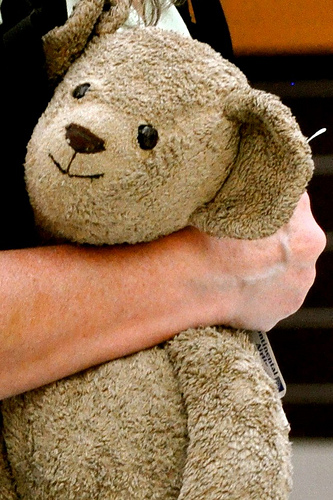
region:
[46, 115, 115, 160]
a large brown nose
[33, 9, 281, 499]
a tan teddy bear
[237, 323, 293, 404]
a white card with black letters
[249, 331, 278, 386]
black letters on white surface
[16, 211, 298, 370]
an arm around the neck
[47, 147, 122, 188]
small mouth of bear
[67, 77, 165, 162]
two black eyes on bear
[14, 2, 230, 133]
a white and black shirt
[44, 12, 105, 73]
a folded ear on bear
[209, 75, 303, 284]
a round ear on bear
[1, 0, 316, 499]
tan teddy bear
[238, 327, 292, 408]
white and black tag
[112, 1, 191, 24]
brown strands of hair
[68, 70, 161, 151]
two black eyes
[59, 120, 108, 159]
brown teddy bear nose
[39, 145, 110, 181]
black lines of mouth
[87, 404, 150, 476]
textured teddy bear fur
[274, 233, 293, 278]
green vein on back of person's hand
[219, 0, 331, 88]
dark orange and black background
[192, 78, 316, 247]
tan teddy bear ear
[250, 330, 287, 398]
a tag on the back of a teddy bear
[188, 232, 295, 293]
a visible blood vein on an arm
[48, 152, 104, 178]
a smile on the face of a toy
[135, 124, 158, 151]
an eyeball of a stuffed animal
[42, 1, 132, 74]
the crumpled ear of a teddy bear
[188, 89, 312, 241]
the cupped ear of a stuffed animal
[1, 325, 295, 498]
the fuzzy body of a stuffed animal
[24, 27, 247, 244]
the face of a teddy bear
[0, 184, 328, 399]
an arm holding a bear tightly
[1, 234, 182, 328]
freckles on a person's arm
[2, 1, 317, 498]
A stuffed animal.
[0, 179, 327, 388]
An arm holding a toy.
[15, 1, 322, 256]
The head of a stuffed teddy bear.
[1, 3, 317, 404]
A child's stuffed teddy bear.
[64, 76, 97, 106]
The eye of a toy bear.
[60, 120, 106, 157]
The nose of a toy teddy bear.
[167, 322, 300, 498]
A teddy bear's furry arm.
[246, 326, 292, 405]
A white tag next to a bear.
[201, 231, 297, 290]
Vein in an arm.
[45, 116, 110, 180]
A teddy bear's smile.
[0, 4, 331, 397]
Hand holding teddy bear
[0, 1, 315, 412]
Hand wrapped around teddy bear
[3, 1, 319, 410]
Hand holding teddy bear head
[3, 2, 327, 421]
Cachasian hand holding tight to teddy bear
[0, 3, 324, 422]
Hand embracing teddy bear around neck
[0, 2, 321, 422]
Arm embracing brown teddy bear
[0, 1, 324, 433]
Beady eyed teddy bear being held by arm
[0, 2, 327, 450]
Arm holding smiling teddy bear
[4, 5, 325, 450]
Arm hugging furry brown teddy bear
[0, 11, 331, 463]
Arm tightly holding smiling brown teddy bear